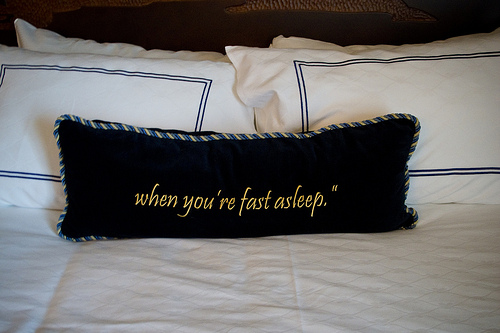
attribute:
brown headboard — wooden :
[0, 0, 499, 57]